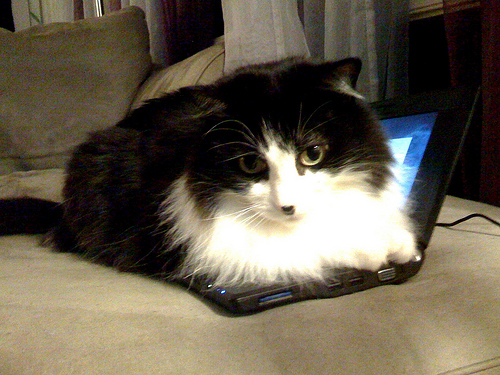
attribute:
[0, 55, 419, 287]
cat — black, white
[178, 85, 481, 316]
laptop — black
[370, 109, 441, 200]
laptop screen — blue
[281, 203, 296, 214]
nose — black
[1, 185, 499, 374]
chair — beige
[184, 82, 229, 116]
ear — furry, of cat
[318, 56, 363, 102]
ear — furry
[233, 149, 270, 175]
eye — yellow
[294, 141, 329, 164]
eye — yellow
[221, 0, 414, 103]
curtain — sheer white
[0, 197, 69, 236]
tail — furry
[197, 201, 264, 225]
whisker — long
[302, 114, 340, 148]
whisker — long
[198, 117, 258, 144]
whisker — long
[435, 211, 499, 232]
cord — black